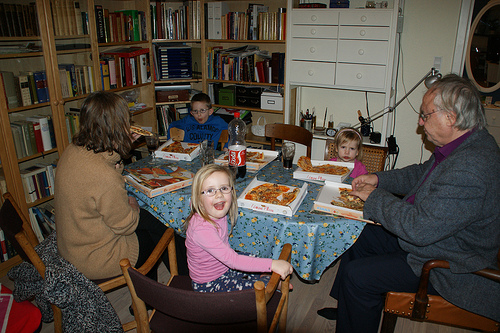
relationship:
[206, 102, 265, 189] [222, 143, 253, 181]
bottle of soda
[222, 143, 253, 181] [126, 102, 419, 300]
soda on table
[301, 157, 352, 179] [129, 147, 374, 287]
pizza on table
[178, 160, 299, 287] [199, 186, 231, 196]
girl wearing in glasses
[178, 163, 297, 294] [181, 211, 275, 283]
girl wearing in shirt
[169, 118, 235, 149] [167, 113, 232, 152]
boy wears shirt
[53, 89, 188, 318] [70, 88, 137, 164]
woman has hair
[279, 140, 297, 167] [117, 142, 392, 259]
glass on table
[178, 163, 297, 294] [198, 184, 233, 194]
girl wears corrective lenses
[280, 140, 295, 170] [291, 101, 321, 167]
glass has liquid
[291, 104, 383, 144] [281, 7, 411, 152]
items on shelves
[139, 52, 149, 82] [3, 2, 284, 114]
book on bookshelf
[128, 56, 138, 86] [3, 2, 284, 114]
book on bookshelf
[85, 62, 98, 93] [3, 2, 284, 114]
book on bookshelf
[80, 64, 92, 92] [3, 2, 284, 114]
book on bookshelf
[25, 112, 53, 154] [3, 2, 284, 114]
book on bookshelf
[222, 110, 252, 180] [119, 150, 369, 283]
bottle on table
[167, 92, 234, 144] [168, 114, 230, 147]
young boy in blue hoodie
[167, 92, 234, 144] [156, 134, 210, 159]
young boy eating pizza